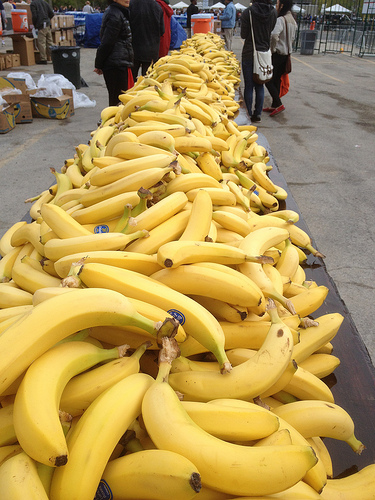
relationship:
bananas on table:
[42, 26, 315, 384] [15, 37, 372, 497]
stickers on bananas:
[85, 222, 112, 233] [42, 26, 315, 384]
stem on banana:
[261, 304, 286, 319] [77, 263, 233, 373]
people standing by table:
[82, 3, 314, 111] [15, 37, 372, 497]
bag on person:
[248, 10, 275, 80] [239, 4, 273, 123]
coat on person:
[91, 10, 137, 78] [239, 4, 273, 123]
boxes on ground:
[1, 66, 80, 129] [1, 34, 373, 314]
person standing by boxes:
[239, 4, 273, 123] [5, 15, 80, 134]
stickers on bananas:
[94, 224, 110, 234] [12, 159, 210, 383]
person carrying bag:
[239, 4, 273, 123] [248, 10, 275, 86]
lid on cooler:
[10, 8, 26, 12] [188, 15, 213, 35]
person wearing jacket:
[239, 4, 273, 123] [92, 1, 135, 74]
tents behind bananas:
[170, 2, 246, 14] [5, 32, 373, 495]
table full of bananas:
[15, 37, 372, 497] [42, 26, 315, 384]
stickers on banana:
[94, 224, 110, 234] [59, 211, 126, 242]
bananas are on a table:
[42, 26, 315, 384] [274, 174, 372, 478]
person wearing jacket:
[239, 4, 273, 123] [238, 3, 277, 56]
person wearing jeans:
[239, 4, 273, 123] [238, 33, 276, 120]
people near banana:
[82, 3, 314, 111] [2, 31, 367, 495]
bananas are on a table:
[42, 26, 315, 384] [294, 213, 373, 480]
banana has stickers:
[2, 31, 367, 495] [94, 224, 110, 234]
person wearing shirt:
[240, 0, 274, 124] [270, 12, 295, 57]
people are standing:
[82, 3, 314, 111] [236, 9, 298, 105]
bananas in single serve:
[42, 26, 315, 384] [74, 261, 236, 374]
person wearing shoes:
[239, 4, 273, 123] [247, 101, 288, 124]